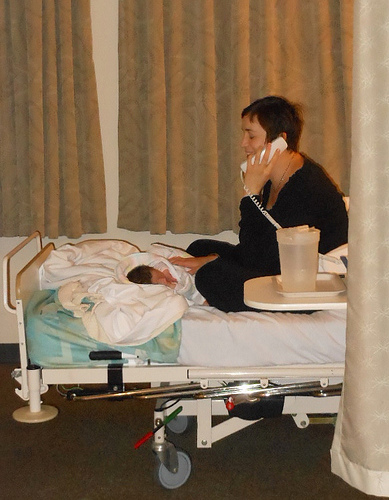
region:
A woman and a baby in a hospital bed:
[106, 93, 361, 351]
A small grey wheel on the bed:
[155, 447, 197, 488]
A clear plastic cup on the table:
[273, 221, 328, 297]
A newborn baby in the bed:
[125, 259, 205, 307]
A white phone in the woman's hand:
[238, 137, 296, 181]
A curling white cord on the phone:
[243, 177, 291, 233]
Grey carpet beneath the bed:
[227, 436, 327, 493]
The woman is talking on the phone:
[213, 97, 349, 275]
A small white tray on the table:
[271, 272, 349, 299]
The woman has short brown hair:
[242, 93, 310, 153]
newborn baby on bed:
[120, 257, 203, 307]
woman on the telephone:
[193, 83, 350, 318]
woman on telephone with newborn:
[108, 77, 356, 318]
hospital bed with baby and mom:
[6, 210, 373, 419]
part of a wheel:
[147, 432, 181, 495]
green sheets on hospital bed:
[20, 280, 192, 381]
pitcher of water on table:
[270, 219, 324, 297]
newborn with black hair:
[115, 251, 205, 304]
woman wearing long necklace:
[221, 85, 330, 275]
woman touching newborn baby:
[111, 228, 232, 311]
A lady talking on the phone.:
[220, 90, 335, 225]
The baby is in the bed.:
[116, 237, 196, 308]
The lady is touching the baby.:
[131, 216, 221, 312]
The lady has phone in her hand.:
[233, 143, 288, 182]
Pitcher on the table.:
[258, 216, 336, 303]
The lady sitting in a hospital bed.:
[9, 222, 383, 390]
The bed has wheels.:
[128, 422, 202, 483]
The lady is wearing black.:
[194, 154, 362, 254]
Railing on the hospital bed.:
[102, 382, 321, 411]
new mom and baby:
[21, 35, 358, 469]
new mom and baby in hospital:
[14, 55, 356, 423]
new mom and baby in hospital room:
[14, 46, 352, 436]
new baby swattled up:
[104, 215, 243, 343]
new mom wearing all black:
[189, 90, 343, 330]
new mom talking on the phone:
[189, 85, 341, 318]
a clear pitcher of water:
[265, 213, 359, 346]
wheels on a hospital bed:
[108, 386, 239, 499]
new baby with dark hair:
[121, 234, 244, 344]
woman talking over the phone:
[195, 96, 342, 314]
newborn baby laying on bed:
[116, 246, 207, 308]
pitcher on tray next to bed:
[273, 223, 348, 300]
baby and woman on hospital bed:
[6, 226, 354, 424]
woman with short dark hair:
[241, 93, 303, 178]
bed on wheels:
[139, 385, 194, 491]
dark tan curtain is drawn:
[0, 27, 111, 239]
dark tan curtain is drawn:
[113, 26, 233, 231]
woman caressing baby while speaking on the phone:
[124, 94, 345, 315]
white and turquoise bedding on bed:
[29, 238, 189, 364]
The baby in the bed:
[122, 252, 199, 304]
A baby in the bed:
[118, 250, 200, 303]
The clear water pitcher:
[271, 229, 323, 299]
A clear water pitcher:
[260, 225, 326, 295]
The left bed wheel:
[150, 443, 199, 491]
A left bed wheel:
[157, 447, 203, 492]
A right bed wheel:
[164, 409, 194, 436]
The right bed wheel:
[166, 407, 196, 439]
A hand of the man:
[162, 240, 224, 282]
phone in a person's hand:
[239, 133, 289, 178]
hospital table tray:
[240, 269, 351, 313]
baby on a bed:
[122, 259, 210, 307]